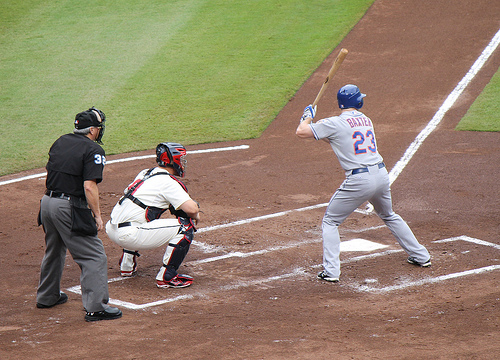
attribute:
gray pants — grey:
[36, 185, 115, 320]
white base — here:
[336, 228, 395, 267]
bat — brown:
[294, 46, 351, 137]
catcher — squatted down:
[104, 140, 203, 293]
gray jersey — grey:
[311, 109, 392, 169]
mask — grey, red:
[150, 141, 191, 179]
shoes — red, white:
[114, 255, 197, 292]